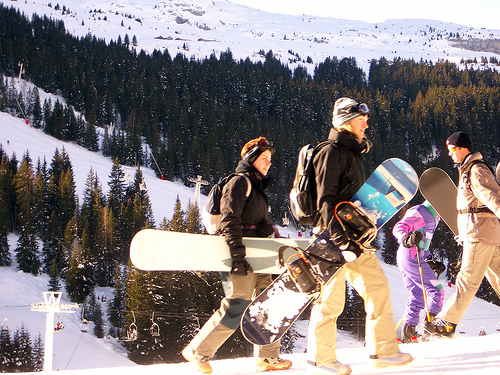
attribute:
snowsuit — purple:
[391, 201, 445, 334]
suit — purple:
[398, 205, 436, 322]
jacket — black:
[313, 125, 367, 232]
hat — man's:
[325, 101, 380, 144]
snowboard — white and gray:
[120, 224, 318, 280]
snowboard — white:
[116, 205, 341, 288]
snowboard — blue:
[240, 157, 419, 347]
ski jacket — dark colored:
[219, 176, 291, 277]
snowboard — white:
[120, 225, 304, 277]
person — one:
[183, 133, 293, 372]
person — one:
[307, 91, 413, 372]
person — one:
[393, 202, 457, 342]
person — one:
[422, 130, 481, 335]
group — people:
[180, 94, 484, 373]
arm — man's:
[311, 141, 351, 244]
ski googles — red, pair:
[243, 136, 273, 162]